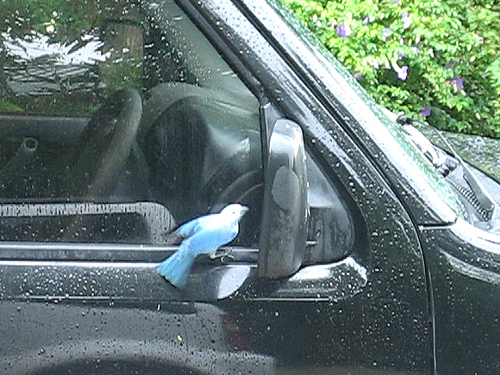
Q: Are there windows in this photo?
A: Yes, there is a window.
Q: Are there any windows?
A: Yes, there is a window.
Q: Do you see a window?
A: Yes, there is a window.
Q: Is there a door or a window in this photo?
A: Yes, there is a window.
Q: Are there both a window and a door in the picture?
A: Yes, there are both a window and a door.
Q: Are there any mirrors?
A: Yes, there is a mirror.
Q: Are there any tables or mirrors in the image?
A: Yes, there is a mirror.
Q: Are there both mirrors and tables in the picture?
A: No, there is a mirror but no tables.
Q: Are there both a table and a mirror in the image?
A: No, there is a mirror but no tables.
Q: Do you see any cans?
A: No, there are no cans.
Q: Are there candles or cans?
A: No, there are no cans or candles.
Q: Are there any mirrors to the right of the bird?
A: Yes, there is a mirror to the right of the bird.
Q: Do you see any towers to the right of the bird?
A: No, there is a mirror to the right of the bird.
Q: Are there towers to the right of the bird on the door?
A: No, there is a mirror to the right of the bird.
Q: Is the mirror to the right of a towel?
A: No, the mirror is to the right of a bird.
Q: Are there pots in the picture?
A: No, there are no pots.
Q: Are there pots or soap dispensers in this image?
A: No, there are no pots or soap dispensers.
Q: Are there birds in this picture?
A: Yes, there is a bird.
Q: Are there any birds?
A: Yes, there is a bird.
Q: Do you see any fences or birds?
A: Yes, there is a bird.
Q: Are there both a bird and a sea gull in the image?
A: No, there is a bird but no seagulls.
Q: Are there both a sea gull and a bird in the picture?
A: No, there is a bird but no seagulls.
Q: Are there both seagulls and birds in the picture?
A: No, there is a bird but no seagulls.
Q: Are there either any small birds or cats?
A: Yes, there is a small bird.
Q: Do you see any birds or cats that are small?
A: Yes, the bird is small.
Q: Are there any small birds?
A: Yes, there is a small bird.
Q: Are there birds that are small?
A: Yes, there is a bird that is small.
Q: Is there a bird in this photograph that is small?
A: Yes, there is a bird that is small.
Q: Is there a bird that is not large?
A: Yes, there is a small bird.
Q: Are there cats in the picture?
A: No, there are no cats.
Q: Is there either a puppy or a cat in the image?
A: No, there are no cats or puppies.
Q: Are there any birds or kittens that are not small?
A: No, there is a bird but it is small.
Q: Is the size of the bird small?
A: Yes, the bird is small.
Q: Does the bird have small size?
A: Yes, the bird is small.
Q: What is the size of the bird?
A: The bird is small.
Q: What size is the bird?
A: The bird is small.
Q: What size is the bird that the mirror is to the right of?
A: The bird is small.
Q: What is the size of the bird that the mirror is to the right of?
A: The bird is small.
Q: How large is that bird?
A: The bird is small.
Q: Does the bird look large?
A: No, the bird is small.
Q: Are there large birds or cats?
A: No, there is a bird but it is small.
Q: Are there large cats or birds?
A: No, there is a bird but it is small.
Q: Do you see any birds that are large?
A: No, there is a bird but it is small.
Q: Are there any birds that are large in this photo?
A: No, there is a bird but it is small.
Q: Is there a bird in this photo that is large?
A: No, there is a bird but it is small.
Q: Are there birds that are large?
A: No, there is a bird but it is small.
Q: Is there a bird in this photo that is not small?
A: No, there is a bird but it is small.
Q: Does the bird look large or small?
A: The bird is small.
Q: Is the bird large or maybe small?
A: The bird is small.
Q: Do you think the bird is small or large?
A: The bird is small.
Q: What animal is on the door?
A: The animal is a bird.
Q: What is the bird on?
A: The bird is on the door.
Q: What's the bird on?
A: The bird is on the door.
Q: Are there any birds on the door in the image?
A: Yes, there is a bird on the door.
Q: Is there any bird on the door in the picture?
A: Yes, there is a bird on the door.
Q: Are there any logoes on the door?
A: No, there is a bird on the door.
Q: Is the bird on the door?
A: Yes, the bird is on the door.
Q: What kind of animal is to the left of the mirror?
A: The animal is a bird.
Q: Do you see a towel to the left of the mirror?
A: No, there is a bird to the left of the mirror.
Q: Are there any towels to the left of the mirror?
A: No, there is a bird to the left of the mirror.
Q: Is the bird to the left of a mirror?
A: Yes, the bird is to the left of a mirror.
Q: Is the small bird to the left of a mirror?
A: Yes, the bird is to the left of a mirror.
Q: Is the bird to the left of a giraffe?
A: No, the bird is to the left of a mirror.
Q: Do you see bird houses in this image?
A: No, there are no bird houses.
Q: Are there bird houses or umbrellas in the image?
A: No, there are no bird houses or umbrellas.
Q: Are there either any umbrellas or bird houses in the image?
A: No, there are no bird houses or umbrellas.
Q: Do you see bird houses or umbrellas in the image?
A: No, there are no bird houses or umbrellas.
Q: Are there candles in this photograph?
A: No, there are no candles.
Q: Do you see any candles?
A: No, there are no candles.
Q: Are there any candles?
A: No, there are no candles.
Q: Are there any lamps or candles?
A: No, there are no candles or lamps.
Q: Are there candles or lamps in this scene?
A: No, there are no candles or lamps.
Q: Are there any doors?
A: Yes, there is a door.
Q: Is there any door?
A: Yes, there is a door.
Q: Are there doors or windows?
A: Yes, there is a door.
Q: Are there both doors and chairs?
A: No, there is a door but no chairs.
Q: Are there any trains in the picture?
A: No, there are no trains.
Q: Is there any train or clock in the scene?
A: No, there are no trains or clocks.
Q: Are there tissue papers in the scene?
A: No, there are no tissue papers.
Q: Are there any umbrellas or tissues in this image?
A: No, there are no tissues or umbrellas.